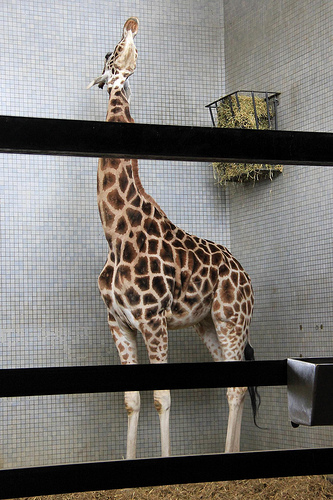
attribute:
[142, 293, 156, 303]
spot — brown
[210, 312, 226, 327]
spot — brown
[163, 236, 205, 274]
spot — brown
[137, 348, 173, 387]
spot — brown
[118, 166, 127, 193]
spot — brown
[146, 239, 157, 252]
spot — brown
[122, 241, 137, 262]
spot — brown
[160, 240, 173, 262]
spot — brown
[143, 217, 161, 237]
spot — brown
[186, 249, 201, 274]
spot — brown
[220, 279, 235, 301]
spot — brown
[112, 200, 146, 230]
spot — brown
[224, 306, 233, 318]
spot — brown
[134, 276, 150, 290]
spot — brown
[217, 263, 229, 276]
spot — brown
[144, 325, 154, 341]
spot — brown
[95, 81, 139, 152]
neck — long